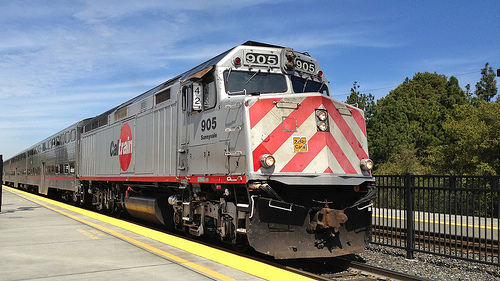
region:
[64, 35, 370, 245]
the locomotive is silver & red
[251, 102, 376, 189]
the red stripes are on a diagonal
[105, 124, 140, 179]
the train has the cal train logo on the side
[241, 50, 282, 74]
the number 905 is on the front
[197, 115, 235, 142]
the same number is on the side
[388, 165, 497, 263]
an iron rail is seperating the trace from the highway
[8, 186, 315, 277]
a yellow stripe lines the curb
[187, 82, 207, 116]
the number 42 is on the mirror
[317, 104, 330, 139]
two headlights are on the front of the train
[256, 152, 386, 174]
two other headlights are on the front of the train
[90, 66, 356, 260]
a train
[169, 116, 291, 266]
a train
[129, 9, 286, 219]
a train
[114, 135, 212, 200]
a train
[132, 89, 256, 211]
a train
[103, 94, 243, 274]
a train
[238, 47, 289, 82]
number 905 on left front of train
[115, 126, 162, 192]
word train in red circle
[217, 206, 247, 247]
front right metal wheel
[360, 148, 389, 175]
left front train headlight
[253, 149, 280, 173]
right front train headlights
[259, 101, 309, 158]
red diagonal stripes on front of train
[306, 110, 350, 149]
two train headlights in middle of the front of train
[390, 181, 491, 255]
black metal fence next to train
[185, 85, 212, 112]
number 42 on right side of train side windows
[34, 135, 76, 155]
line of windows on passenger train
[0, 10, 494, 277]
A train station scene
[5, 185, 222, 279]
This is the platform area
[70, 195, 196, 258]
A yellow stripe is painted on the platform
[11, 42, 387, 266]
This is a train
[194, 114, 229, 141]
This is the train's number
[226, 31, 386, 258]
The front of the train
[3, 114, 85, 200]
These are passenger train cars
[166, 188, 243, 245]
The train's wheels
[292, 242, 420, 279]
A set of train tracks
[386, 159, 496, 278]
A fence is near the tracks